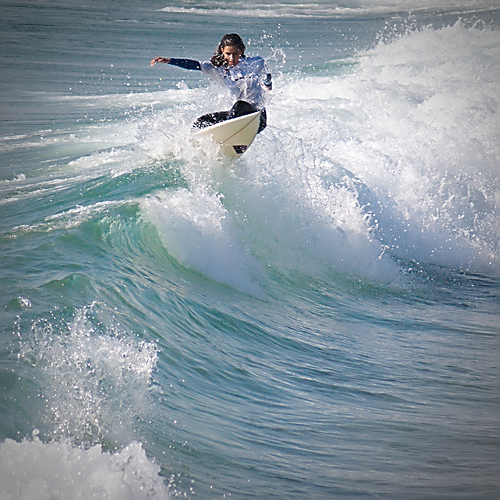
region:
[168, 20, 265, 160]
Person in the water.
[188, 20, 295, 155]
Person is surfing in water.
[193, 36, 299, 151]
Person is riding the wave.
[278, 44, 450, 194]
Big wave in the ocean.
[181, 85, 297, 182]
Person on top of surfboard.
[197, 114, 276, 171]
The surfboard is white.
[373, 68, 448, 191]
The water is white.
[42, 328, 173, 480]
Waves is splashing in the water.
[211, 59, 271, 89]
Shirt is white.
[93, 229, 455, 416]
The water is blue.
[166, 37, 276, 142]
girl is on surfboard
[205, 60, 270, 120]
girl has white shirt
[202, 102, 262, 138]
girl has blue pants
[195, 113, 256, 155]
girl's board is white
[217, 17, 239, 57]
girl has brown hair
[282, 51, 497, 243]
large and white wave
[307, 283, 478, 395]
water is crystal blue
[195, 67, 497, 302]
large wave on water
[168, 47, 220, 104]
right arm is extended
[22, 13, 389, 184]
blue and choppy surf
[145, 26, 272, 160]
surfer girl in sea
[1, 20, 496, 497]
white waves on the sea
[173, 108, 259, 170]
white surfboard on the ocean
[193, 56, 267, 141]
wetsuit of surfboarder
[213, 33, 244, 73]
large blonde hair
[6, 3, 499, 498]
light blue ocean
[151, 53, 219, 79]
right arm of surfboarder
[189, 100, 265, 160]
black wetsuit of surfboarder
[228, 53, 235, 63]
little nose of surfboarder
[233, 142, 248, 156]
black symbol on surfboard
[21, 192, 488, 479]
the curl of a wave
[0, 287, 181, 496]
water splashing in foreground of photo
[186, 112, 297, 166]
bottom of the surfboard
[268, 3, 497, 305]
white water topping the wave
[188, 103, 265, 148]
black pants of a wet suit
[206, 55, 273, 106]
white short sleeved shirt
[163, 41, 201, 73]
long sleeveof black wet suit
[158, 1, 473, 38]
white topped waves coming from the rear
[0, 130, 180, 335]
water is clear and clean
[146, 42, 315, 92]
arms extended for balance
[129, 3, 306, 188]
the woman is surfing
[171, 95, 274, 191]
the board is white